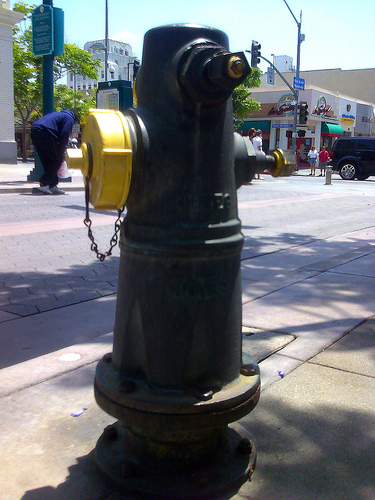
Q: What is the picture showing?
A: It is showing a sidewalk.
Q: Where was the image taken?
A: It was taken at the sidewalk.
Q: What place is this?
A: It is a sidewalk.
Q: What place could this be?
A: It is a sidewalk.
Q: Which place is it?
A: It is a sidewalk.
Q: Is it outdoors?
A: Yes, it is outdoors.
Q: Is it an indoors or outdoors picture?
A: It is outdoors.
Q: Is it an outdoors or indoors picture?
A: It is outdoors.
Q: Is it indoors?
A: No, it is outdoors.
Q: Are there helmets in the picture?
A: No, there are no helmets.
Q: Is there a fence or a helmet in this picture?
A: No, there are no helmets or fences.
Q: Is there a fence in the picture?
A: No, there are no fences.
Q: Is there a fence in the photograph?
A: No, there are no fences.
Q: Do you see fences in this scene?
A: No, there are no fences.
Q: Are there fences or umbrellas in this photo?
A: No, there are no fences or umbrellas.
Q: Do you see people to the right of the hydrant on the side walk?
A: Yes, there are people to the right of the hydrant.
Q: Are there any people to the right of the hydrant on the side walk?
A: Yes, there are people to the right of the hydrant.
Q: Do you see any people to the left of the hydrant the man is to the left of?
A: No, the people are to the right of the hydrant.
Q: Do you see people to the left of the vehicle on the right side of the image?
A: Yes, there are people to the left of the vehicle.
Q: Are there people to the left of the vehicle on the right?
A: Yes, there are people to the left of the vehicle.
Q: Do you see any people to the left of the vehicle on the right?
A: Yes, there are people to the left of the vehicle.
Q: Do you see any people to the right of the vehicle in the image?
A: No, the people are to the left of the vehicle.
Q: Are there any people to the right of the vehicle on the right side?
A: No, the people are to the left of the vehicle.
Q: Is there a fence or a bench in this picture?
A: No, there are no fences or benches.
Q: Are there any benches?
A: No, there are no benches.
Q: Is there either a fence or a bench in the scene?
A: No, there are no benches or fences.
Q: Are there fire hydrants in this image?
A: Yes, there is a fire hydrant.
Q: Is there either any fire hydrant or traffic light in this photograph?
A: Yes, there is a fire hydrant.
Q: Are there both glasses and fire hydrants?
A: No, there is a fire hydrant but no glasses.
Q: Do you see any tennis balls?
A: No, there are no tennis balls.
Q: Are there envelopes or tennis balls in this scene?
A: No, there are no tennis balls or envelopes.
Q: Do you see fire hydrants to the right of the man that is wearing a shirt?
A: Yes, there is a fire hydrant to the right of the man.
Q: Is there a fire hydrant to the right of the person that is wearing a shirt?
A: Yes, there is a fire hydrant to the right of the man.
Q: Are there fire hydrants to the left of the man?
A: No, the fire hydrant is to the right of the man.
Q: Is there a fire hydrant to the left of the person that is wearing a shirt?
A: No, the fire hydrant is to the right of the man.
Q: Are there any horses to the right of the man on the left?
A: No, there is a fire hydrant to the right of the man.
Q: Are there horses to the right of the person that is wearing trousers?
A: No, there is a fire hydrant to the right of the man.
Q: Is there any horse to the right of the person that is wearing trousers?
A: No, there is a fire hydrant to the right of the man.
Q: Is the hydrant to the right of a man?
A: Yes, the hydrant is to the right of a man.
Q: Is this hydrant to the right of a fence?
A: No, the hydrant is to the right of a man.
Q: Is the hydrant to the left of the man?
A: No, the hydrant is to the right of the man.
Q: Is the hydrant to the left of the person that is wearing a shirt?
A: No, the hydrant is to the right of the man.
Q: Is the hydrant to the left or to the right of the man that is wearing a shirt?
A: The hydrant is to the right of the man.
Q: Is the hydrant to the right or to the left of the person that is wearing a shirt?
A: The hydrant is to the right of the man.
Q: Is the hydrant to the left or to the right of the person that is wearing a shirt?
A: The hydrant is to the right of the man.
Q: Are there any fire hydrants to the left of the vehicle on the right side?
A: Yes, there is a fire hydrant to the left of the vehicle.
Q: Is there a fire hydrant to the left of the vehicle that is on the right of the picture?
A: Yes, there is a fire hydrant to the left of the vehicle.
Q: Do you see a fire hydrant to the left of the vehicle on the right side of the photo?
A: Yes, there is a fire hydrant to the left of the vehicle.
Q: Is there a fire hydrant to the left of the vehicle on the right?
A: Yes, there is a fire hydrant to the left of the vehicle.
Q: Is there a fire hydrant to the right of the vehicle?
A: No, the fire hydrant is to the left of the vehicle.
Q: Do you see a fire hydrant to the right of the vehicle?
A: No, the fire hydrant is to the left of the vehicle.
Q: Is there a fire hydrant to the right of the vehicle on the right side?
A: No, the fire hydrant is to the left of the vehicle.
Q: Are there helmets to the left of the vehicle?
A: No, there is a fire hydrant to the left of the vehicle.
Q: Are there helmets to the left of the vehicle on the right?
A: No, there is a fire hydrant to the left of the vehicle.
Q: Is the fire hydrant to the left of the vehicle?
A: Yes, the fire hydrant is to the left of the vehicle.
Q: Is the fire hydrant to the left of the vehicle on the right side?
A: Yes, the fire hydrant is to the left of the vehicle.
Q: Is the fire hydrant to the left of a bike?
A: No, the fire hydrant is to the left of the vehicle.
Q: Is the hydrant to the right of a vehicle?
A: No, the hydrant is to the left of a vehicle.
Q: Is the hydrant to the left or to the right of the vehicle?
A: The hydrant is to the left of the vehicle.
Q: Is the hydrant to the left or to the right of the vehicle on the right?
A: The hydrant is to the left of the vehicle.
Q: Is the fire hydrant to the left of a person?
A: Yes, the fire hydrant is to the left of a person.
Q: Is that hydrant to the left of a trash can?
A: No, the hydrant is to the left of a person.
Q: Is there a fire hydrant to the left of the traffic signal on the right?
A: Yes, there is a fire hydrant to the left of the signal light.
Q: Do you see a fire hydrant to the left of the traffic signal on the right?
A: Yes, there is a fire hydrant to the left of the signal light.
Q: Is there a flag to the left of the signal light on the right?
A: No, there is a fire hydrant to the left of the traffic light.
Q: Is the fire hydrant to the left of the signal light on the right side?
A: Yes, the fire hydrant is to the left of the signal light.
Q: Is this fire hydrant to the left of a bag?
A: No, the fire hydrant is to the left of the signal light.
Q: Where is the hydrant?
A: The hydrant is on the sidewalk.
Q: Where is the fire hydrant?
A: The hydrant is on the sidewalk.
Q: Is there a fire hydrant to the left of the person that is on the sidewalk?
A: Yes, there is a fire hydrant to the left of the person.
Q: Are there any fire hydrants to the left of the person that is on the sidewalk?
A: Yes, there is a fire hydrant to the left of the person.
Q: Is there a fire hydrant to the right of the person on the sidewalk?
A: No, the fire hydrant is to the left of the person.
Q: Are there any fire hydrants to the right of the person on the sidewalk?
A: No, the fire hydrant is to the left of the person.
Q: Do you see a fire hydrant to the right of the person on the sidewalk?
A: No, the fire hydrant is to the left of the person.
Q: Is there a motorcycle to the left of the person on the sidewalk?
A: No, there is a fire hydrant to the left of the person.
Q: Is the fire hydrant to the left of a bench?
A: No, the fire hydrant is to the left of a person.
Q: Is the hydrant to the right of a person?
A: No, the hydrant is to the left of a person.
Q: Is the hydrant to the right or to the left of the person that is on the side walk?
A: The hydrant is to the left of the person.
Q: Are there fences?
A: No, there are no fences.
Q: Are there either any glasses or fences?
A: No, there are no fences or glasses.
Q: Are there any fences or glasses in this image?
A: No, there are no fences or glasses.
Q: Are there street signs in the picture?
A: Yes, there is a street sign.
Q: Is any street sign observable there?
A: Yes, there is a street sign.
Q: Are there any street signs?
A: Yes, there is a street sign.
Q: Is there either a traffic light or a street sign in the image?
A: Yes, there is a street sign.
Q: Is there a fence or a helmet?
A: No, there are no fences or helmets.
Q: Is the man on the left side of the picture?
A: Yes, the man is on the left of the image.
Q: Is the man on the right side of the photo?
A: No, the man is on the left of the image.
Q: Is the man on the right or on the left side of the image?
A: The man is on the left of the image.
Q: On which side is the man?
A: The man is on the left of the image.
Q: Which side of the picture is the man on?
A: The man is on the left of the image.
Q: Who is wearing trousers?
A: The man is wearing trousers.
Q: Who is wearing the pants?
A: The man is wearing trousers.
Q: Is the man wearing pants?
A: Yes, the man is wearing pants.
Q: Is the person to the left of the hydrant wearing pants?
A: Yes, the man is wearing pants.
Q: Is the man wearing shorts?
A: No, the man is wearing pants.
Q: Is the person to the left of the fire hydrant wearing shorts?
A: No, the man is wearing pants.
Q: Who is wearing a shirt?
A: The man is wearing a shirt.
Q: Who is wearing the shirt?
A: The man is wearing a shirt.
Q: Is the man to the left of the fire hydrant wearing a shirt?
A: Yes, the man is wearing a shirt.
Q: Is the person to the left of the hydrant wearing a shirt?
A: Yes, the man is wearing a shirt.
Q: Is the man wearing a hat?
A: No, the man is wearing a shirt.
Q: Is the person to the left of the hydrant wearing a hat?
A: No, the man is wearing a shirt.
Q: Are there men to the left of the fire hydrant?
A: Yes, there is a man to the left of the fire hydrant.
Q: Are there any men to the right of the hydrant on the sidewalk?
A: No, the man is to the left of the hydrant.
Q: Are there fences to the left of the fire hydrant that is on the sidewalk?
A: No, there is a man to the left of the hydrant.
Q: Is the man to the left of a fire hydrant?
A: Yes, the man is to the left of a fire hydrant.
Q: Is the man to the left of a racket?
A: No, the man is to the left of a fire hydrant.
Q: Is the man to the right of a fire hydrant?
A: No, the man is to the left of a fire hydrant.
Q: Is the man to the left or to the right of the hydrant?
A: The man is to the left of the hydrant.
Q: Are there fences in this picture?
A: No, there are no fences.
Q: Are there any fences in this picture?
A: No, there are no fences.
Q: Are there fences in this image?
A: No, there are no fences.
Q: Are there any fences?
A: No, there are no fences.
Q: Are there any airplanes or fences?
A: No, there are no fences or airplanes.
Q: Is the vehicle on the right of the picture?
A: Yes, the vehicle is on the right of the image.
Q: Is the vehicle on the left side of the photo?
A: No, the vehicle is on the right of the image.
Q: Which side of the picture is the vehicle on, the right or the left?
A: The vehicle is on the right of the image.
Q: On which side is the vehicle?
A: The vehicle is on the right of the image.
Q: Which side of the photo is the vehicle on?
A: The vehicle is on the right of the image.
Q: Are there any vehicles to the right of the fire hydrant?
A: Yes, there is a vehicle to the right of the fire hydrant.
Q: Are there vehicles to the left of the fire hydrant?
A: No, the vehicle is to the right of the fire hydrant.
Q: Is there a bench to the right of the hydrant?
A: No, there is a vehicle to the right of the hydrant.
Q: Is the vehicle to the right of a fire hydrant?
A: Yes, the vehicle is to the right of a fire hydrant.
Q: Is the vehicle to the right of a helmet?
A: No, the vehicle is to the right of a fire hydrant.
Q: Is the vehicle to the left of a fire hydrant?
A: No, the vehicle is to the right of a fire hydrant.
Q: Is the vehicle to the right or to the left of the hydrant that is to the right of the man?
A: The vehicle is to the right of the hydrant.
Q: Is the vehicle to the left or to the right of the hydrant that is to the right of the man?
A: The vehicle is to the right of the hydrant.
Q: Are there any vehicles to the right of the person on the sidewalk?
A: Yes, there is a vehicle to the right of the person.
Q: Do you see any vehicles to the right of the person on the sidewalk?
A: Yes, there is a vehicle to the right of the person.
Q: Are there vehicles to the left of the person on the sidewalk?
A: No, the vehicle is to the right of the person.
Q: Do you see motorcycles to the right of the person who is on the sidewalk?
A: No, there is a vehicle to the right of the person.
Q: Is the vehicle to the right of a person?
A: Yes, the vehicle is to the right of a person.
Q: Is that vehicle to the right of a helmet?
A: No, the vehicle is to the right of a person.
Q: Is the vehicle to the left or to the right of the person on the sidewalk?
A: The vehicle is to the right of the person.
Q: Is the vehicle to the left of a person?
A: No, the vehicle is to the right of a person.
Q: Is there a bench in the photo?
A: No, there are no benches.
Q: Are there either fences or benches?
A: No, there are no benches or fences.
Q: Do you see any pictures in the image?
A: No, there are no pictures.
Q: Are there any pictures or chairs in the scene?
A: No, there are no pictures or chairs.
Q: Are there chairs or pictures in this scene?
A: No, there are no pictures or chairs.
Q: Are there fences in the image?
A: No, there are no fences.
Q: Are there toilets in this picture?
A: No, there are no toilets.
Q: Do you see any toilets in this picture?
A: No, there are no toilets.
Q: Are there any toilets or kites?
A: No, there are no toilets or kites.